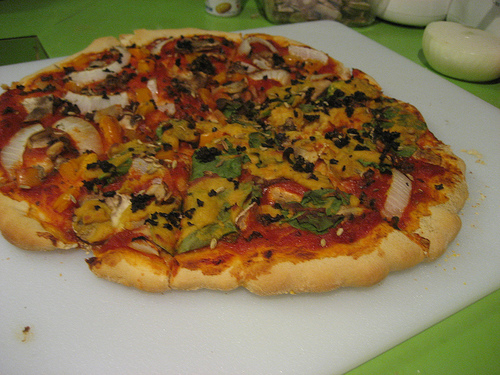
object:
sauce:
[92, 229, 163, 260]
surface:
[0, 0, 499, 371]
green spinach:
[188, 137, 254, 179]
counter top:
[0, 0, 499, 373]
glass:
[257, 0, 391, 28]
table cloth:
[0, 0, 500, 374]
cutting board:
[0, 20, 500, 374]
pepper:
[433, 181, 445, 194]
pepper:
[205, 188, 219, 199]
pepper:
[268, 200, 283, 209]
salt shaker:
[203, 0, 243, 17]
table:
[1, 0, 500, 374]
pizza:
[84, 142, 195, 295]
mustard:
[337, 198, 365, 216]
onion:
[419, 19, 499, 83]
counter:
[0, 0, 500, 373]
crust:
[83, 244, 175, 294]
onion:
[381, 167, 414, 222]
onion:
[53, 116, 105, 155]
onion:
[3, 122, 43, 179]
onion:
[64, 91, 130, 114]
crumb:
[21, 324, 31, 335]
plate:
[0, 19, 499, 373]